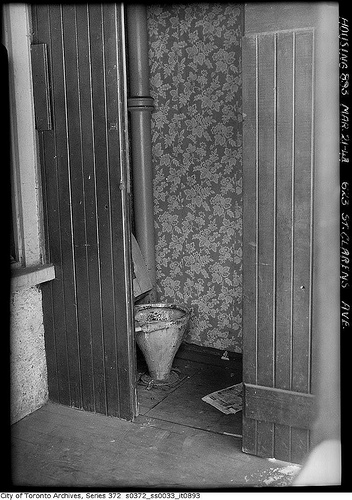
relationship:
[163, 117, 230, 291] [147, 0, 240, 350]
pattern on wall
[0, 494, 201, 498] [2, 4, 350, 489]
serial identification of photo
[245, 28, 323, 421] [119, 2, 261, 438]
surface of doorway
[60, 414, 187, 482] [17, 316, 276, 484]
surface of floor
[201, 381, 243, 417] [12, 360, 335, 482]
newspaper on ground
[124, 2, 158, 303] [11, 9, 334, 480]
pipe in bathroom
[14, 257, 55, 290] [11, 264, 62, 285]
surface of window sill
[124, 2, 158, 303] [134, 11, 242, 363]
pipe along wall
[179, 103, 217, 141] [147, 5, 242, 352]
flower on wallpaper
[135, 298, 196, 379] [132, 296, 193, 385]
dirt inside of toilet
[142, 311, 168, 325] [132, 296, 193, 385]
feces inside of toilet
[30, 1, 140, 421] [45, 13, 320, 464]
door on bathroom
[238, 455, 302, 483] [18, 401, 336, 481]
white paint on floor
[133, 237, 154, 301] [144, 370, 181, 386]
lid covering hole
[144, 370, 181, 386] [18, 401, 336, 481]
hole in floor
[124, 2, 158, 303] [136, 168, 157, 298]
pipe used for water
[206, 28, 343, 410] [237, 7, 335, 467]
wood used for door